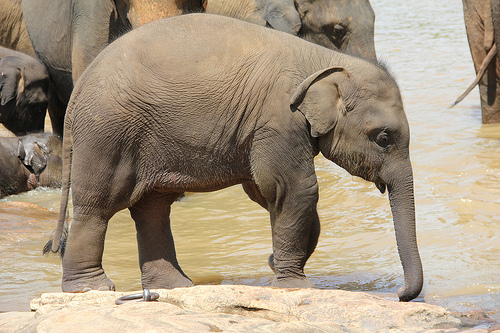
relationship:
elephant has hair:
[51, 12, 425, 303] [358, 55, 397, 78]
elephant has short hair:
[1, 47, 49, 137] [25, 128, 63, 144]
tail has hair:
[41, 75, 88, 258] [43, 232, 70, 256]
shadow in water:
[189, 269, 426, 315] [0, 0, 498, 332]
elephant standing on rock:
[51, 12, 425, 303] [0, 281, 465, 332]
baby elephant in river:
[1, 47, 49, 134] [0, 0, 498, 332]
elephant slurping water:
[51, 12, 425, 303] [0, 0, 498, 332]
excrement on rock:
[117, 291, 160, 303] [0, 281, 465, 332]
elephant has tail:
[51, 12, 425, 303] [41, 75, 88, 258]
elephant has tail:
[450, 0, 500, 126] [450, 38, 499, 109]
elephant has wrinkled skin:
[51, 12, 425, 303] [102, 65, 287, 143]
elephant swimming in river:
[1, 47, 49, 137] [0, 0, 498, 332]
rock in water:
[0, 281, 465, 332] [0, 0, 498, 332]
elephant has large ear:
[51, 12, 425, 303] [288, 62, 355, 144]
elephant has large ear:
[201, 0, 381, 74] [263, 0, 302, 39]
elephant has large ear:
[1, 47, 49, 134] [1, 65, 25, 105]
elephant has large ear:
[1, 47, 49, 137] [17, 136, 55, 180]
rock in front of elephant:
[0, 281, 465, 332] [51, 12, 425, 303]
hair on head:
[348, 48, 395, 81] [298, 50, 423, 192]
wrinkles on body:
[102, 65, 287, 143] [51, 12, 425, 303]